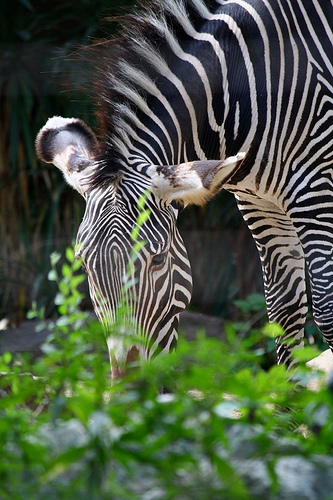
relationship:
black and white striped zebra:
[302, 240, 327, 256] [41, 80, 331, 342]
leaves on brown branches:
[149, 402, 190, 457] [103, 392, 308, 500]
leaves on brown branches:
[89, 422, 161, 475] [139, 387, 235, 424]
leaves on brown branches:
[170, 373, 251, 427] [17, 410, 104, 497]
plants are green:
[35, 366, 328, 471] [55, 476, 104, 500]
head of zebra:
[73, 183, 194, 407] [244, 157, 309, 206]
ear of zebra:
[141, 145, 248, 200] [83, 173, 330, 364]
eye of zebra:
[146, 246, 172, 279] [163, 101, 282, 178]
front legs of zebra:
[222, 175, 331, 357] [149, 46, 255, 88]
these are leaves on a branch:
[52, 339, 105, 457] [67, 445, 161, 500]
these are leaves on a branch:
[139, 468, 186, 500] [170, 412, 257, 465]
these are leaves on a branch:
[166, 336, 254, 409] [157, 375, 250, 465]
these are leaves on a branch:
[99, 444, 281, 496] [121, 369, 209, 421]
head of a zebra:
[73, 183, 194, 407] [282, 108, 307, 147]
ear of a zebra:
[141, 145, 248, 200] [281, 83, 313, 116]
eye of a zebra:
[146, 246, 172, 279] [282, 215, 315, 235]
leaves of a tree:
[154, 341, 239, 438] [214, 430, 309, 482]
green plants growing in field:
[59, 348, 105, 421] [3, 302, 320, 495]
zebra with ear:
[21, 2, 331, 430] [141, 145, 248, 200]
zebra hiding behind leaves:
[21, 2, 331, 430] [9, 242, 306, 495]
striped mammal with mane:
[32, 4, 319, 388] [88, 1, 190, 158]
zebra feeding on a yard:
[21, 2, 331, 430] [3, 319, 314, 496]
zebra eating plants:
[21, 2, 331, 430] [10, 346, 316, 494]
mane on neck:
[84, 2, 225, 159] [115, 18, 275, 219]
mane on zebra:
[84, 2, 225, 159] [21, 2, 331, 430]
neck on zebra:
[115, 18, 275, 219] [21, 2, 331, 430]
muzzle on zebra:
[108, 322, 175, 414] [47, 6, 330, 378]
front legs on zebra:
[222, 175, 331, 357] [21, 2, 331, 430]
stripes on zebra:
[152, 4, 276, 152] [21, 2, 331, 430]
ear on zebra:
[40, 101, 107, 198] [40, 5, 331, 345]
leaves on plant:
[0, 338, 246, 452] [12, 186, 316, 489]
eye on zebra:
[146, 246, 172, 279] [21, 1, 329, 376]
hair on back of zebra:
[70, 30, 160, 161] [21, 1, 329, 376]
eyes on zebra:
[74, 248, 170, 269] [21, 2, 331, 430]